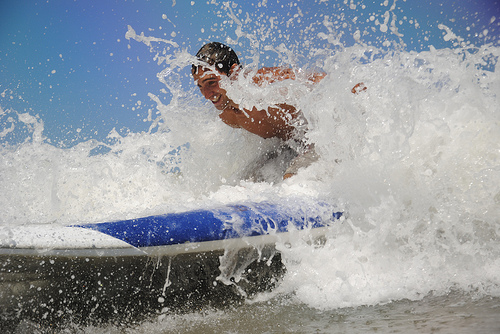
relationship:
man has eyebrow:
[189, 41, 367, 182] [200, 74, 222, 82]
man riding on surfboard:
[168, 45, 398, 210] [7, 140, 378, 276]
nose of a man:
[201, 84, 213, 99] [188, 38, 367, 181]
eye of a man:
[207, 78, 216, 84] [188, 38, 367, 181]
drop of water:
[121, 22, 142, 42] [253, 267, 484, 332]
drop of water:
[90, 40, 99, 47] [396, 181, 498, 236]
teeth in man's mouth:
[210, 89, 224, 103] [201, 86, 226, 110]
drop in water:
[104, 51, 116, 59] [3, 49, 498, 331]